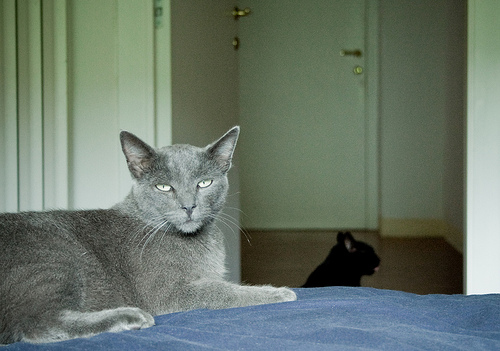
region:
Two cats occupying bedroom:
[0, 127, 496, 348]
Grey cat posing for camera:
[106, 124, 247, 234]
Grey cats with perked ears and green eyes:
[113, 122, 247, 236]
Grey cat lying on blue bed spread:
[0, 126, 309, 349]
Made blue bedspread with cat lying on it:
[4, 244, 498, 349]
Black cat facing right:
[301, 230, 385, 285]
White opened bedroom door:
[153, 2, 260, 287]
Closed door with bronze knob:
[231, 4, 379, 234]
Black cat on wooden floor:
[241, 228, 463, 294]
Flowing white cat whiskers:
[124, 208, 254, 260]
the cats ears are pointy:
[92, 88, 262, 275]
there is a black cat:
[307, 198, 405, 307]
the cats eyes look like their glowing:
[136, 149, 223, 203]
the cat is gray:
[0, 96, 302, 349]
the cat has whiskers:
[90, 96, 271, 265]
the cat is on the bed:
[10, 92, 298, 336]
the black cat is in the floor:
[309, 203, 404, 325]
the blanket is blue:
[308, 299, 388, 349]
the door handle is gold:
[207, 1, 389, 113]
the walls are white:
[387, 26, 451, 164]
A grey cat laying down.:
[1, 122, 297, 342]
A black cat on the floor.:
[298, 228, 381, 290]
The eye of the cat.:
[153, 180, 173, 193]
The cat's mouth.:
[170, 202, 206, 232]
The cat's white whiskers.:
[219, 210, 256, 245]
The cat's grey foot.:
[63, 306, 154, 331]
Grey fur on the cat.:
[50, 244, 94, 286]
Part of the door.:
[288, 107, 336, 155]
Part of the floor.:
[263, 242, 276, 266]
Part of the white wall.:
[406, 88, 437, 145]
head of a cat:
[106, 117, 251, 238]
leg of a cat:
[57, 296, 146, 338]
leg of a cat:
[166, 270, 306, 338]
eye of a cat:
[145, 170, 182, 201]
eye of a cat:
[199, 168, 234, 186]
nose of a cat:
[177, 192, 214, 218]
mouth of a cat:
[162, 207, 212, 235]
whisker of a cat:
[138, 196, 169, 247]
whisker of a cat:
[178, 199, 253, 252]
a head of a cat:
[63, 91, 282, 249]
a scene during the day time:
[5, 5, 497, 348]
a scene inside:
[7, 8, 484, 350]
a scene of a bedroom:
[2, 2, 497, 349]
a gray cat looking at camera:
[0, 115, 309, 348]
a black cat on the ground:
[288, 216, 393, 300]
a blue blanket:
[5, 279, 498, 349]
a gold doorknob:
[346, 61, 376, 83]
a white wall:
[3, 5, 240, 231]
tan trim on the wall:
[373, 208, 495, 263]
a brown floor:
[237, 214, 479, 305]